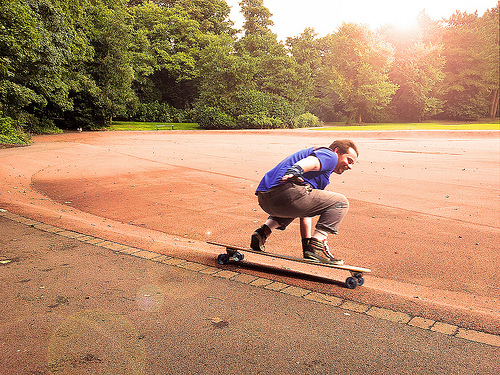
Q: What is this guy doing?
A: Skateboarding.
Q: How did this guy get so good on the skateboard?
A: Practice.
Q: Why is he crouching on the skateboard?
A: For better balance.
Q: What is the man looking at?
A: The pathway.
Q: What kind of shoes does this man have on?
A: Sneakers.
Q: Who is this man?
A: A skateboarder.